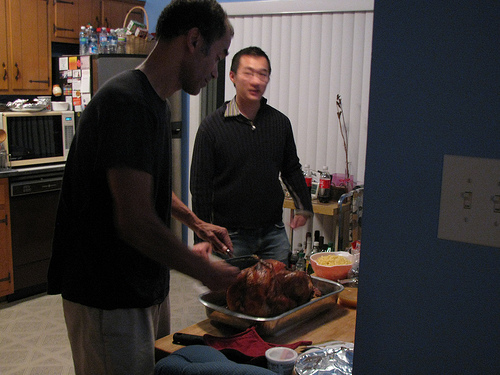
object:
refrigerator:
[52, 50, 194, 270]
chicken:
[213, 249, 325, 321]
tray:
[193, 266, 346, 336]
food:
[313, 251, 353, 271]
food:
[206, 247, 323, 321]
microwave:
[0, 107, 76, 171]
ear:
[183, 23, 205, 55]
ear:
[224, 66, 238, 85]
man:
[191, 47, 312, 261]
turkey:
[226, 254, 321, 316]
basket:
[106, 11, 218, 85]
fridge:
[67, 36, 167, 104]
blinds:
[224, 11, 375, 253]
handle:
[173, 329, 213, 344]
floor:
[1, 259, 293, 373]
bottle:
[320, 163, 332, 205]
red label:
[312, 175, 338, 192]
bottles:
[74, 21, 133, 58]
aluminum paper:
[292, 341, 356, 374]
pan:
[199, 273, 342, 333]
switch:
[458, 189, 474, 211]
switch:
[487, 192, 497, 213]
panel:
[435, 152, 499, 250]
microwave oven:
[0, 109, 77, 169]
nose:
[248, 76, 263, 86]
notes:
[60, 57, 89, 114]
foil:
[306, 352, 327, 368]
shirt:
[32, 64, 203, 311]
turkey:
[209, 251, 351, 307]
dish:
[9, 105, 49, 113]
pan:
[197, 273, 340, 340]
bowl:
[308, 249, 355, 279]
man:
[49, 2, 237, 340]